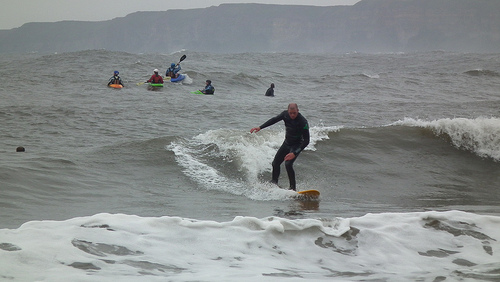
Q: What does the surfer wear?
A: Black wetsuit.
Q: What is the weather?
A: Overcast and cloudy.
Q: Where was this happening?
A: The ocean.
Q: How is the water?
A: Frothy surf and cresting waves.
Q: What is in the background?
A: Mountains.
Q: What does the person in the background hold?
A: A paddle.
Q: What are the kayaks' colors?
A: Blue, green and orange.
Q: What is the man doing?
A: The man is surfing on the water.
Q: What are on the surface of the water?
A: Bubbles in the ocean.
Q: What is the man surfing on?
A: Waves on the ocean.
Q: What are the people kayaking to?
A: Mountain at the end of ocean.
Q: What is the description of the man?
A: White man wearing black bodysuit standing upright on board in water.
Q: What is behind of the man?
A: Five people on boards with paddles in water.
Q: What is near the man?
A: Crashing waves in the ocean.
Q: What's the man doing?
A: Surfing.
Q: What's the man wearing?
A: Wetsuit.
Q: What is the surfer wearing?
A: A wet suit.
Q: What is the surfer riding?
A: A wave.